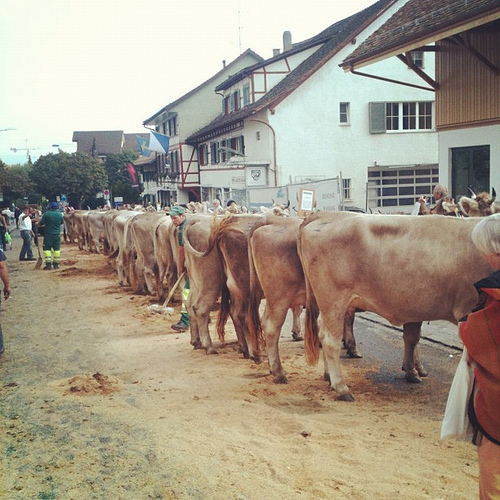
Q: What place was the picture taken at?
A: It was taken at the pavement.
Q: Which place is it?
A: It is a pavement.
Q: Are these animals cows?
A: Yes, all the animals are cows.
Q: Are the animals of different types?
A: No, all the animals are cows.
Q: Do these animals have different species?
A: No, all the animals are cows.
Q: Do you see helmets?
A: No, there are no helmets.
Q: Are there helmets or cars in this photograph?
A: No, there are no helmets or cars.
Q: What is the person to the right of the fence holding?
A: The person is holding the bag.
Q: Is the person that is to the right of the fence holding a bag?
A: Yes, the person is holding a bag.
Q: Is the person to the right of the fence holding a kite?
A: No, the person is holding a bag.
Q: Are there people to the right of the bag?
A: Yes, there is a person to the right of the bag.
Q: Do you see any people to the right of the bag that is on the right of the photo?
A: Yes, there is a person to the right of the bag.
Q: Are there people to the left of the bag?
A: No, the person is to the right of the bag.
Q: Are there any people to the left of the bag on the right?
A: No, the person is to the right of the bag.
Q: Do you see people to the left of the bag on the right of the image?
A: No, the person is to the right of the bag.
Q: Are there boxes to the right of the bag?
A: No, there is a person to the right of the bag.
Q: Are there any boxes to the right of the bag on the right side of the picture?
A: No, there is a person to the right of the bag.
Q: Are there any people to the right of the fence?
A: Yes, there is a person to the right of the fence.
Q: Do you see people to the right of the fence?
A: Yes, there is a person to the right of the fence.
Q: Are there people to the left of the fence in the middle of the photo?
A: No, the person is to the right of the fence.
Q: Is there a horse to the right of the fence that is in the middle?
A: No, there is a person to the right of the fence.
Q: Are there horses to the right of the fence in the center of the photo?
A: No, there is a person to the right of the fence.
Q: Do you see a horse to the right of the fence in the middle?
A: No, there is a person to the right of the fence.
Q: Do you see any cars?
A: No, there are no cars.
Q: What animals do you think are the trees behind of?
A: The trees are behind the cows.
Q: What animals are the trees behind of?
A: The trees are behind the cows.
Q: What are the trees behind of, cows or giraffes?
A: The trees are behind cows.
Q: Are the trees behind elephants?
A: No, the trees are behind the cows.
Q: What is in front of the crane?
A: The trees are in front of the crane.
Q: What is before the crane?
A: The trees are in front of the crane.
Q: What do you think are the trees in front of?
A: The trees are in front of the crane.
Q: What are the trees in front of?
A: The trees are in front of the crane.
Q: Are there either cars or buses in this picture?
A: No, there are no cars or buses.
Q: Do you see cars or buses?
A: No, there are no cars or buses.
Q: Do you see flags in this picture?
A: Yes, there is a flag.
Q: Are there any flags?
A: Yes, there is a flag.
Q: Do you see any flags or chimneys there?
A: Yes, there is a flag.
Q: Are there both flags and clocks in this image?
A: No, there is a flag but no clocks.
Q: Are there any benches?
A: No, there are no benches.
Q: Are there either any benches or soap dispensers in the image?
A: No, there are no benches or soap dispensers.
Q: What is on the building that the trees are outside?
A: The flag is on the building.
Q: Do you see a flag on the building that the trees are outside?
A: Yes, there is a flag on the building.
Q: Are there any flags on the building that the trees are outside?
A: Yes, there is a flag on the building.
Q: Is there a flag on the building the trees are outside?
A: Yes, there is a flag on the building.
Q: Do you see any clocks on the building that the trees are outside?
A: No, there is a flag on the building.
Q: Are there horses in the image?
A: No, there are no horses.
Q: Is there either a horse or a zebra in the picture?
A: No, there are no horses or zebras.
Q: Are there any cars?
A: No, there are no cars.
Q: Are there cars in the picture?
A: No, there are no cars.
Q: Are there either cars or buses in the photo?
A: No, there are no cars or buses.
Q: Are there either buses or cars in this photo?
A: No, there are no cars or buses.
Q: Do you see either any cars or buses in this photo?
A: No, there are no cars or buses.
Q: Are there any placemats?
A: No, there are no placemats.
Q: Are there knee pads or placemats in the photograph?
A: No, there are no placemats or knee pads.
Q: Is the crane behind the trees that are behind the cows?
A: Yes, the crane is behind the trees.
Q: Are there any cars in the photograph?
A: No, there are no cars.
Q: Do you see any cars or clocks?
A: No, there are no cars or clocks.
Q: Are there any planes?
A: No, there are no planes.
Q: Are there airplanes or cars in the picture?
A: No, there are no airplanes or cars.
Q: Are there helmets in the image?
A: No, there are no helmets.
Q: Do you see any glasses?
A: No, there are no glasses.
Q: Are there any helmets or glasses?
A: No, there are no glasses or helmets.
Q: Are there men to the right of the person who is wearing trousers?
A: Yes, there is a man to the right of the person.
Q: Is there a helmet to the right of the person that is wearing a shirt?
A: No, there is a man to the right of the person.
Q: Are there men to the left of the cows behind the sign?
A: Yes, there is a man to the left of the cows.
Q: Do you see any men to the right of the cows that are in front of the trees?
A: No, the man is to the left of the cows.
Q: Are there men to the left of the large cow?
A: Yes, there is a man to the left of the cow.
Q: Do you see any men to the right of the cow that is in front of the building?
A: No, the man is to the left of the cow.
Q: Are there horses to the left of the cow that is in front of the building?
A: No, there is a man to the left of the cow.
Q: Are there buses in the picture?
A: No, there are no buses.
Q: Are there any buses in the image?
A: No, there are no buses.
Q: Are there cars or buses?
A: No, there are no buses or cars.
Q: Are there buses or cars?
A: No, there are no buses or cars.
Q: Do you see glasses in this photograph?
A: No, there are no glasses.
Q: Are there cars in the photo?
A: No, there are no cars.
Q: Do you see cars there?
A: No, there are no cars.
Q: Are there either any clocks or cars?
A: No, there are no cars or clocks.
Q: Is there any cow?
A: Yes, there is a cow.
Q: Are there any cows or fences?
A: Yes, there is a cow.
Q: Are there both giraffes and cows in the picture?
A: No, there is a cow but no giraffes.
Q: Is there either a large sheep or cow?
A: Yes, there is a large cow.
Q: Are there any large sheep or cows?
A: Yes, there is a large cow.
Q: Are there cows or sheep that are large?
A: Yes, the cow is large.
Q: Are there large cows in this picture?
A: Yes, there is a large cow.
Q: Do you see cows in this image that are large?
A: Yes, there is a cow that is large.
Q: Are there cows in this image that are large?
A: Yes, there is a cow that is large.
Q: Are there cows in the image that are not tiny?
A: Yes, there is a large cow.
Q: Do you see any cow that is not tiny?
A: Yes, there is a large cow.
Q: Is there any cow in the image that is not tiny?
A: Yes, there is a large cow.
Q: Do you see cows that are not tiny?
A: Yes, there is a large cow.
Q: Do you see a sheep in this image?
A: No, there is no sheep.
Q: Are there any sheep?
A: No, there are no sheep.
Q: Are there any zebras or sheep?
A: No, there are no sheep or zebras.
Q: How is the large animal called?
A: The animal is a cow.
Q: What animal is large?
A: The animal is a cow.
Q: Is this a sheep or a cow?
A: This is a cow.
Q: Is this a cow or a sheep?
A: This is a cow.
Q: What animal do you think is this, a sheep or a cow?
A: This is a cow.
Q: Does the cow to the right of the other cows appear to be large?
A: Yes, the cow is large.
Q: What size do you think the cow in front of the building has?
A: The cow has large size.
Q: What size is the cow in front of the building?
A: The cow is large.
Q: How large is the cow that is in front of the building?
A: The cow is large.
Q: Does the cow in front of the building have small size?
A: No, the cow is large.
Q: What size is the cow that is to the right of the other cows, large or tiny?
A: The cow is large.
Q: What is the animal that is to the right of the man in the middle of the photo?
A: The animal is a cow.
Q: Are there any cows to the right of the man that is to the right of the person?
A: Yes, there is a cow to the right of the man.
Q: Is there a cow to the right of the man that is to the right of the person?
A: Yes, there is a cow to the right of the man.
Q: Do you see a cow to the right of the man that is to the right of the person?
A: Yes, there is a cow to the right of the man.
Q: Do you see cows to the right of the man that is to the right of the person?
A: Yes, there is a cow to the right of the man.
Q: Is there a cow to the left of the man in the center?
A: No, the cow is to the right of the man.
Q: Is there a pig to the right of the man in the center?
A: No, there is a cow to the right of the man.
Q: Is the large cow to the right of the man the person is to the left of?
A: Yes, the cow is to the right of the man.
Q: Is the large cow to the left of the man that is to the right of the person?
A: No, the cow is to the right of the man.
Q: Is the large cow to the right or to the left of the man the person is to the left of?
A: The cow is to the right of the man.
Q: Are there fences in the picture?
A: Yes, there is a fence.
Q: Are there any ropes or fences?
A: Yes, there is a fence.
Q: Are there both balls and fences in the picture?
A: No, there is a fence but no balls.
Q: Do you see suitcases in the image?
A: No, there are no suitcases.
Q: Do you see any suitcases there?
A: No, there are no suitcases.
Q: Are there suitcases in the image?
A: No, there are no suitcases.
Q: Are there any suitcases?
A: No, there are no suitcases.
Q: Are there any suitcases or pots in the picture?
A: No, there are no suitcases or pots.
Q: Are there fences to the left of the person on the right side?
A: Yes, there is a fence to the left of the person.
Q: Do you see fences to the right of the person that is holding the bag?
A: No, the fence is to the left of the person.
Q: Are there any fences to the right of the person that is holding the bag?
A: No, the fence is to the left of the person.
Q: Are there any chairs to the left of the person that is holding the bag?
A: No, there is a fence to the left of the person.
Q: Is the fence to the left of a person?
A: Yes, the fence is to the left of a person.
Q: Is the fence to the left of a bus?
A: No, the fence is to the left of a person.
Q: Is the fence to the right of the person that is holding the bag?
A: No, the fence is to the left of the person.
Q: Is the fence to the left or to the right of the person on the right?
A: The fence is to the left of the person.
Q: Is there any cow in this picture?
A: Yes, there are cows.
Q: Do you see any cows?
A: Yes, there are cows.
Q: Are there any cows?
A: Yes, there are cows.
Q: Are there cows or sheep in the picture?
A: Yes, there are cows.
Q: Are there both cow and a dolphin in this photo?
A: No, there are cows but no dolphins.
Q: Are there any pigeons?
A: No, there are no pigeons.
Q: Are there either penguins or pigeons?
A: No, there are no pigeons or penguins.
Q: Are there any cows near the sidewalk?
A: Yes, there are cows near the sidewalk.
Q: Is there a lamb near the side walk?
A: No, there are cows near the side walk.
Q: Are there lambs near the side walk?
A: No, there are cows near the side walk.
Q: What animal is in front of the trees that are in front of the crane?
A: The cows are in front of the trees.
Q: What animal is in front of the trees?
A: The cows are in front of the trees.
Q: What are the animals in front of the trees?
A: The animals are cows.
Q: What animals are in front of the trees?
A: The animals are cows.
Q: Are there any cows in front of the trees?
A: Yes, there are cows in front of the trees.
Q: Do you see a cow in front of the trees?
A: Yes, there are cows in front of the trees.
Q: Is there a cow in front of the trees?
A: Yes, there are cows in front of the trees.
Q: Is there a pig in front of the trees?
A: No, there are cows in front of the trees.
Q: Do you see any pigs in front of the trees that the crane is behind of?
A: No, there are cows in front of the trees.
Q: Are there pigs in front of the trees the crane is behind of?
A: No, there are cows in front of the trees.